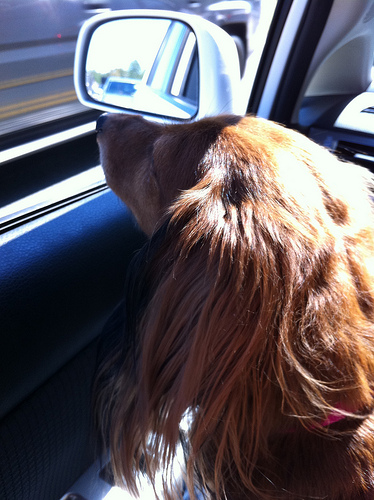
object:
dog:
[92, 113, 373, 497]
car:
[2, 1, 373, 497]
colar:
[270, 389, 373, 436]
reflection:
[81, 15, 197, 122]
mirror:
[72, 8, 240, 128]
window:
[2, 1, 280, 251]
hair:
[98, 113, 373, 495]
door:
[105, 24, 199, 120]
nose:
[95, 109, 109, 136]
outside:
[2, 4, 94, 115]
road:
[2, 53, 91, 142]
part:
[138, 14, 151, 66]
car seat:
[56, 400, 211, 498]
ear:
[92, 195, 320, 473]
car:
[89, 78, 141, 99]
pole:
[6, 89, 78, 119]